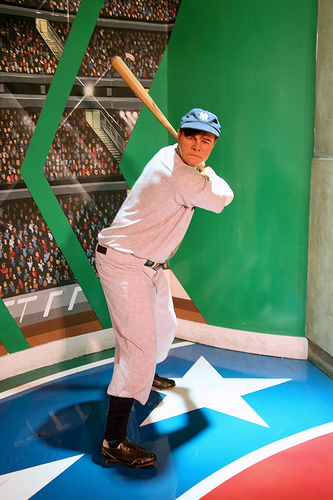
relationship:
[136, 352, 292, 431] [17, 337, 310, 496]
star on floor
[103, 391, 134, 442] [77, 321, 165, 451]
black socks on leg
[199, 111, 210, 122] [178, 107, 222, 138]
logo on baseball cap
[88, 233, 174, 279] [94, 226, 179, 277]
belt around waist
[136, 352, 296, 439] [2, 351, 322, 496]
star against background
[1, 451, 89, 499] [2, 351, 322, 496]
star against background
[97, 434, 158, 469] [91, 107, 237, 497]
shoe on player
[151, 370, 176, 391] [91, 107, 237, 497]
shoe on player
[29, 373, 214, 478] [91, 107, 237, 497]
shadow of player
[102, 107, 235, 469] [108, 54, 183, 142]
babe ruth holding baseball bat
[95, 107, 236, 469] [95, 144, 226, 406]
babe ruth wearing a uniform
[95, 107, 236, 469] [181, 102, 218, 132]
babe ruth wearing a cap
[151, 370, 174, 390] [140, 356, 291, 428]
shoe on star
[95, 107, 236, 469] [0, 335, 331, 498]
babe ruth on floor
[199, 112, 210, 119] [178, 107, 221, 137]
logo on baseball cap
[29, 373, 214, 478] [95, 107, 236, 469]
shadow cast by babe ruth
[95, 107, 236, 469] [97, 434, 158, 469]
babe ruth wearing shoe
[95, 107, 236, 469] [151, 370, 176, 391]
babe ruth wearing shoe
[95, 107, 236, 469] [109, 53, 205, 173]
babe ruth holding baseball bat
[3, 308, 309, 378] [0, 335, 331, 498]
base on floor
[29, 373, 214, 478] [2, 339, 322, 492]
shadow on ground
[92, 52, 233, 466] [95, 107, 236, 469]
figure of a babe ruth